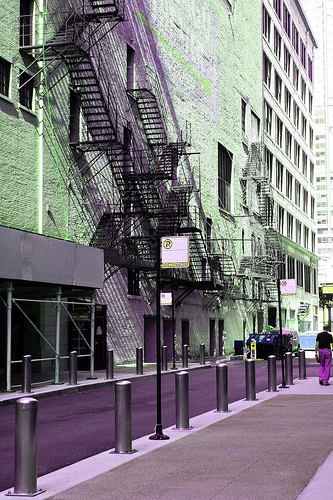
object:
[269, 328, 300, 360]
van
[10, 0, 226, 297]
ladders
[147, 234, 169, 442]
pole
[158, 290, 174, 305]
sign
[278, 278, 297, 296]
sign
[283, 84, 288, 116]
window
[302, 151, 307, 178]
window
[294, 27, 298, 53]
window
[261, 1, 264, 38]
window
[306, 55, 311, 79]
window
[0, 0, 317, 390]
building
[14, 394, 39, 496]
pole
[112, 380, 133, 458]
pole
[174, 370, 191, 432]
pole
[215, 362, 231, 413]
pole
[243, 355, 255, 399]
pole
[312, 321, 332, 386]
man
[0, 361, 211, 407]
sidewalk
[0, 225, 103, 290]
awning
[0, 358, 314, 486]
road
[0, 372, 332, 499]
sidewalk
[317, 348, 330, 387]
pants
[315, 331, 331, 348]
shirt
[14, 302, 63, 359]
post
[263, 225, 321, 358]
storefront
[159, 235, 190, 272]
sign